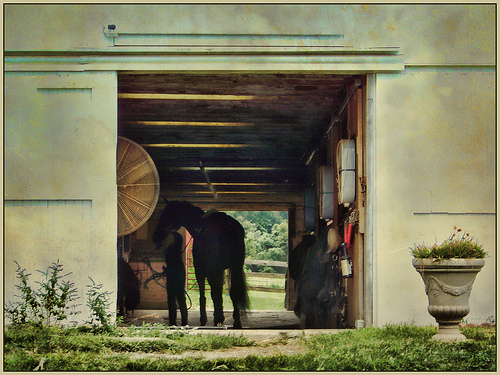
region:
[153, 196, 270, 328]
horse standing in the stable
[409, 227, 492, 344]
plant in a cement planter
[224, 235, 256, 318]
long hair on the tail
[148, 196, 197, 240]
head is turned to the side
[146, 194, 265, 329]
person standing by the horse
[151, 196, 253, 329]
horse is taller than the human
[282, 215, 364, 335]
various objects hanging on the wall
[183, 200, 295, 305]
stable door is open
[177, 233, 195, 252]
strap hanging down from the horse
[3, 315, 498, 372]
green grass on the ground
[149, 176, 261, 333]
this is a horse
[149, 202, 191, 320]
this is a person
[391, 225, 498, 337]
this is plant pot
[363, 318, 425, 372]
this is grass outside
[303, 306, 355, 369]
this is grass outside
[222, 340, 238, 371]
this is grass outside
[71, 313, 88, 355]
this is grass outside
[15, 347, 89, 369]
this is grass outside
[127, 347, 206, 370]
this is grass outside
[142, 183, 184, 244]
head of a horse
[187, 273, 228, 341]
legs of a horse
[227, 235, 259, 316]
tail of a horse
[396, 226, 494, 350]
stone pot on a ground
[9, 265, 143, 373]
bushes on the ground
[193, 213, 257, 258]
body of a horse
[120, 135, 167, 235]
a circle wood on side of building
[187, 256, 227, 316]
legs of a horse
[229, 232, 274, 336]
tail of a horse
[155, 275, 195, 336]
leg of a person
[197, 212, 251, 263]
body of a horse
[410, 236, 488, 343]
ceramic pot on grass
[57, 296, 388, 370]
bunch of grass on a field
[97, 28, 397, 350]
entrance to a building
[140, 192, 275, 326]
a horse and a person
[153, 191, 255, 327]
horse in the stall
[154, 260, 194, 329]
man wearing black pants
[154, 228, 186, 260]
man wearing a white shirt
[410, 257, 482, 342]
a stone planter with grass inside.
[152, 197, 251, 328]
A horse inside a stable.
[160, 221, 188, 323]
A person standing near a horse.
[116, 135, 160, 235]
A wheel in the stables.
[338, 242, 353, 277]
A white bag hanging from a wall.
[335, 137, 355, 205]
A white picture hanging on the wall.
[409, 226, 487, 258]
grass growing from a stone planter.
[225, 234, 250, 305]
The tail on the horse.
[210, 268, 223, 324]
The leg of the horse.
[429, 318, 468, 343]
The base of the planter.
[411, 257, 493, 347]
large grey concrete pot